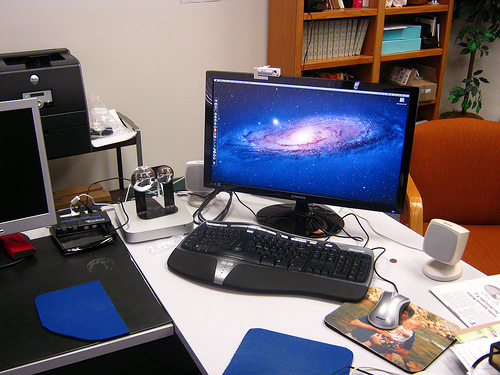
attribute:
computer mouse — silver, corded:
[366, 289, 411, 331]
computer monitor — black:
[205, 68, 421, 220]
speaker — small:
[421, 214, 470, 282]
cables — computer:
[192, 184, 279, 242]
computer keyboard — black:
[168, 204, 378, 314]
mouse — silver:
[363, 290, 412, 332]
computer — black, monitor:
[185, 64, 442, 230]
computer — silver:
[186, 57, 469, 333]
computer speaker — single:
[422, 217, 470, 284]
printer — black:
[10, 55, 107, 143]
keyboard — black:
[145, 202, 398, 312]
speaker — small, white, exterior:
[404, 213, 492, 280]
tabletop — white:
[0, 174, 496, 373]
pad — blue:
[36, 284, 150, 356]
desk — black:
[18, 221, 226, 373]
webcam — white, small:
[253, 64, 280, 82]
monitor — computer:
[199, 72, 419, 216]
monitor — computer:
[1, 97, 56, 234]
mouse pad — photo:
[330, 285, 462, 373]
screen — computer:
[203, 68, 417, 214]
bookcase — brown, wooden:
[272, 2, 453, 129]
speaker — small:
[180, 157, 218, 199]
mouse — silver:
[363, 292, 429, 332]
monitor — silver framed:
[1, 104, 68, 245]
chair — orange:
[421, 114, 498, 277]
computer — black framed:
[137, 47, 464, 358]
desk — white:
[104, 189, 497, 373]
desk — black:
[0, 223, 174, 370]